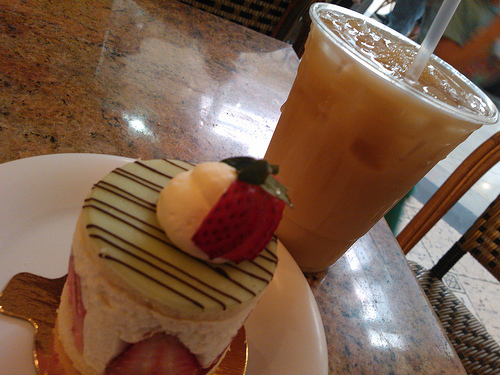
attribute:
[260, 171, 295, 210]
leaf — green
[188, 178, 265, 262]
strawberry slice — red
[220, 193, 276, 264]
strawberry slice — red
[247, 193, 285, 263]
strawberry slice — red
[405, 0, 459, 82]
drinking straw — clear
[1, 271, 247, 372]
sauce — brown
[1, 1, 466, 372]
counter top — marble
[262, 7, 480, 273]
ice tea — full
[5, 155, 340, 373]
plate — white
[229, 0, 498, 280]
drink — beige 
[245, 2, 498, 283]
clear cup — clear 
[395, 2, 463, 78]
clear straw — clear 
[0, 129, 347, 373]
plate — white, round 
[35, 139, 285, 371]
pastry — white, brown, green 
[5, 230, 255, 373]
gold platter — gold 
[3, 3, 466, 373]
granite counter — black , granite 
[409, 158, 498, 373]
chair — Brown , black 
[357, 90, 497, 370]
flooring — black , brown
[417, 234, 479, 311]
square design — small , square  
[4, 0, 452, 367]
table — brown , granite top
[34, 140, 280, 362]
cookie — green , brown 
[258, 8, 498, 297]
plastic cup — plastic 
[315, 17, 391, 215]
beverage — orange 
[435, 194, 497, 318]
wicker chair — brown , black 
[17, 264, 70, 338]
foil tray — gold , small 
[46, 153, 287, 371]
appetizer dish — cylinder 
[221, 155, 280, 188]
leaf — small, green